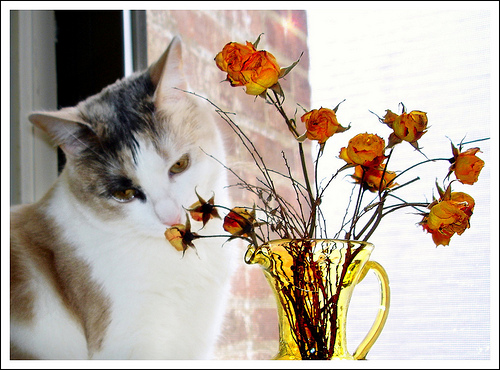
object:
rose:
[221, 199, 269, 249]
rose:
[290, 97, 352, 157]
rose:
[401, 211, 449, 249]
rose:
[368, 103, 432, 160]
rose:
[343, 163, 401, 195]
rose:
[432, 177, 474, 211]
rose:
[405, 192, 469, 239]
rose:
[441, 135, 486, 185]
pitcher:
[243, 238, 391, 360]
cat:
[9, 36, 228, 361]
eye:
[108, 189, 136, 203]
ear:
[25, 111, 94, 153]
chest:
[92, 204, 235, 360]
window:
[305, 0, 497, 360]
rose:
[212, 32, 264, 72]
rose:
[238, 50, 304, 108]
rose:
[217, 54, 251, 86]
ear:
[145, 36, 186, 102]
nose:
[163, 210, 202, 261]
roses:
[178, 183, 219, 231]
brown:
[4, 212, 35, 326]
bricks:
[261, 15, 308, 74]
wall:
[144, 10, 314, 360]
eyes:
[167, 152, 191, 179]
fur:
[9, 34, 237, 360]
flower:
[334, 131, 390, 169]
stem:
[207, 203, 250, 229]